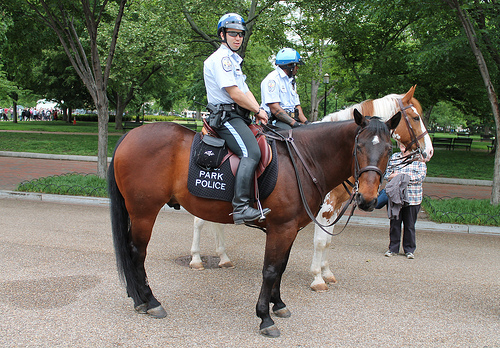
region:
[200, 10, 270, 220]
a seated man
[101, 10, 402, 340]
a mounted officer on horse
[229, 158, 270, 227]
a black leather riding boot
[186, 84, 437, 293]
a light brown and white horse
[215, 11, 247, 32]
a dark blue helmet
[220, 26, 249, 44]
The man has glasses on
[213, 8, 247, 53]
The man has a helmet on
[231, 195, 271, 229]
The man has a boot on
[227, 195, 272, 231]
The man has a black boot on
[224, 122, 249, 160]
Line on a man's pant leg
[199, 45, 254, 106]
The man is wearing a shirt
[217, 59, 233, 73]
Badge on a shirt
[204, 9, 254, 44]
man has blue helmet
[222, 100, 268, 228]
blue and black pants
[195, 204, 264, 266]
man has black shoes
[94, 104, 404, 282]
horse is dark brown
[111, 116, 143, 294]
horse has black tail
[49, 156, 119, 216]
green and leafy plants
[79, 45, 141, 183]
tree has thin trunk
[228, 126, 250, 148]
the man is wearing pants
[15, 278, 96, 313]
stain in the street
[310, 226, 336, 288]
the horses legs are long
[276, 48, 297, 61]
man is wearing a helmet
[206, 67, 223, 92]
the blue shirt the man is wearing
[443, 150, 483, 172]
the lawn is green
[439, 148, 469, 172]
the green lawn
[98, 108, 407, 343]
brown police horse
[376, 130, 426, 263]
person standing near a horse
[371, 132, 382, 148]
white spot on a brown horse's face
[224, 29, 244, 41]
sunglasses on a policeman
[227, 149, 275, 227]
right boot of a policeman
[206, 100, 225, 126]
gun in a holster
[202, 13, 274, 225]
man on a brown horse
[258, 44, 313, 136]
man on a chesnut and white horse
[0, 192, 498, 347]
walkway at a park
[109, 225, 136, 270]
a black tail on the horse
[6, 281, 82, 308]
a stain in the street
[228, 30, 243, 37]
man is wearing sun glasses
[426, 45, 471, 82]
the green leaves on the tree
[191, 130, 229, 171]
black bag on side of black horse saddle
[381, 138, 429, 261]
person in plaid shirt and black jeans standing next to horse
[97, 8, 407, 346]
police officer on top of horse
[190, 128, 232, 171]
black bag attached to black horse saddle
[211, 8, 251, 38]
blue helmet on man's head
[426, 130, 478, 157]
wooden park bench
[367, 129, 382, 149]
white mark in between horse's eyes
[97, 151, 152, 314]
black horse hair tail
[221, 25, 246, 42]
sunglasses on police officer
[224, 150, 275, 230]
black riding boot of police officer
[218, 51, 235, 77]
badge on shoulder sleeve of police officer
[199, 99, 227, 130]
gun in holster on hip of police officer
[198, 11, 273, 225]
cop on a dark brown horse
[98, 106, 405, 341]
dark brown police horse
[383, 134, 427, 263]
person standing on the road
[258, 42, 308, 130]
person on a white and brown horse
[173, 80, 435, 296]
brown and white horse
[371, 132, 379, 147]
white mark on a brown horse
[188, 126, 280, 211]
saddle on a brown horse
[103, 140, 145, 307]
black tail of a horse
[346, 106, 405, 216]
head of a dark brown horse